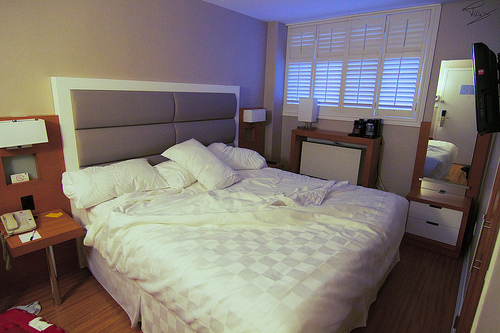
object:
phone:
[0, 210, 38, 272]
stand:
[405, 184, 473, 259]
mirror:
[424, 58, 477, 186]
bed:
[60, 140, 406, 333]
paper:
[18, 230, 42, 243]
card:
[9, 172, 29, 184]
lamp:
[0, 118, 50, 150]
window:
[271, 8, 438, 121]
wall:
[1, 1, 277, 124]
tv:
[472, 41, 500, 136]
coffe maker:
[348, 118, 382, 139]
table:
[288, 126, 382, 188]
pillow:
[160, 138, 241, 190]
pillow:
[206, 141, 269, 170]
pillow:
[153, 159, 198, 188]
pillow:
[61, 158, 170, 210]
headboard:
[51, 77, 242, 171]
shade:
[298, 98, 318, 122]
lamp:
[296, 98, 318, 131]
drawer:
[408, 200, 465, 229]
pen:
[30, 230, 36, 242]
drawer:
[404, 217, 461, 248]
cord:
[1, 230, 14, 272]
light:
[243, 108, 267, 123]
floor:
[356, 248, 460, 333]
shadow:
[57, 272, 100, 304]